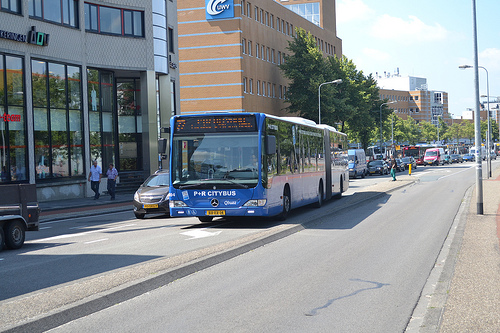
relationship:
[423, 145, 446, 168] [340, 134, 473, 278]
van on street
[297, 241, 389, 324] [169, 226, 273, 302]
patch on street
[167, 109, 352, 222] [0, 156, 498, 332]
bus on road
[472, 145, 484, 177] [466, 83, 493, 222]
sticker on a pole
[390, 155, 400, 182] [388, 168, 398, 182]
man wearing pants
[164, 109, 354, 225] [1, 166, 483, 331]
bus on street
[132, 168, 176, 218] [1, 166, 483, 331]
car on street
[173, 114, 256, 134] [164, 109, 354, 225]
destination sign on bus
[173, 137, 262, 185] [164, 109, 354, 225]
wind shield on bus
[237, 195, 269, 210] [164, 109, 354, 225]
head light on bus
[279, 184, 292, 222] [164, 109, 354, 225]
tire on bus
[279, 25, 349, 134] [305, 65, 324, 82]
tree with leaves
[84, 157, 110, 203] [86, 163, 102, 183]
man wearing shirt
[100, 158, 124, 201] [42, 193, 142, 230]
man walking on sidewalk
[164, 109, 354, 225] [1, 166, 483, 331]
bus driving down street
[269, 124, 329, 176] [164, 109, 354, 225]
windows on side of bus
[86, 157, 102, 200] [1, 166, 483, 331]
man walking down street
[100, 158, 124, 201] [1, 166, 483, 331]
man walking down street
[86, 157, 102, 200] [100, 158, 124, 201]
man beside man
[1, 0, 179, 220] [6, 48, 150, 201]
building with windows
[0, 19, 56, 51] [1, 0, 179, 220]
name on building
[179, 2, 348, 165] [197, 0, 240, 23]
building with sign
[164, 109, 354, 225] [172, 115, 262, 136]
bus with destination sign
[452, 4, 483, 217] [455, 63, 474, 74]
poles with streetlight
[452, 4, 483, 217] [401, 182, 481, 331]
poles on sidewalk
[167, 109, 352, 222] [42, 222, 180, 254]
bus on pavement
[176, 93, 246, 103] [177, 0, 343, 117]
blue line on building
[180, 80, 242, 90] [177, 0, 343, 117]
blue line on building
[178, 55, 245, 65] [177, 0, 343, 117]
blue line on building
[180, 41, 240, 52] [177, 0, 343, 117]
blue line on building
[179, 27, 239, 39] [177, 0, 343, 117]
blue line on building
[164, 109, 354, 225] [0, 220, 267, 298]
bus on street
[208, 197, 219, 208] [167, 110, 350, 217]
brand on bus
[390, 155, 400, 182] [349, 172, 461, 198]
man on street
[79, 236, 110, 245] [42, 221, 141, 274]
white line on asphalt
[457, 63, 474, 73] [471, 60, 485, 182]
light on pole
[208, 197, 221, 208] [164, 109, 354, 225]
brand on bus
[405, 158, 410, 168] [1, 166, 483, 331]
pole on street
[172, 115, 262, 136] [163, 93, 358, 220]
destination sign on bus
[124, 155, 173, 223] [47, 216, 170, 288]
car on street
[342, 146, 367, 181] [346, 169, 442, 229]
van parked on street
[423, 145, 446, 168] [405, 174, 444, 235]
van parked on street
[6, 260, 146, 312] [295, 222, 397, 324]
median in street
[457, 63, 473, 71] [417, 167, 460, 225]
light over street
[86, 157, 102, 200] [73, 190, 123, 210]
man walking on sidewalk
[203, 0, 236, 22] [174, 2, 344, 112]
sign on building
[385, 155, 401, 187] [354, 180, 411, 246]
man crossing street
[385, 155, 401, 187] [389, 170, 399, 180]
man wearing pants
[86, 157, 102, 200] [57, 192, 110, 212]
man are on sidewalk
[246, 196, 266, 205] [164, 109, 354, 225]
headlight of bus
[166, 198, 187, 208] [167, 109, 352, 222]
headlight of bus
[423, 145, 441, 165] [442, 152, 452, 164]
van in front of car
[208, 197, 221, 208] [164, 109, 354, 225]
brand on front of bus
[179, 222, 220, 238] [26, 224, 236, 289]
arrow painted on street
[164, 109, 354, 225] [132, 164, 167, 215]
bus in front of car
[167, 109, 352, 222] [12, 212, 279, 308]
bus on road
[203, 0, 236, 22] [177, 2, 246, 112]
sign on wall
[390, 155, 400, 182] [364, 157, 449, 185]
man standing on intersection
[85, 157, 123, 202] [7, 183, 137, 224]
couple walking on sidewalk